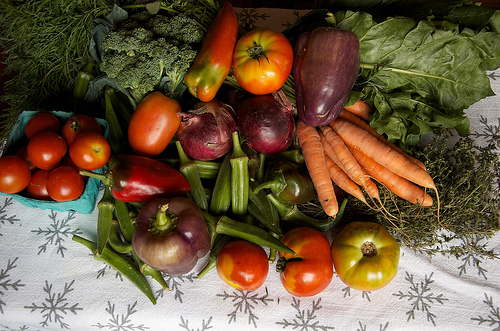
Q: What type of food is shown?
A: Vegetables.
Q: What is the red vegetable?
A: Tomato.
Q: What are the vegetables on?
A: Table cloth.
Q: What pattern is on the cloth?
A: Snowflakes.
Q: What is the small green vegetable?
A: Okra.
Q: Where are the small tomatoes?
A: Cardboard container.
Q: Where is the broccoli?
A: Above the carton.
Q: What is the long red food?
A: Pepper.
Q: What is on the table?
A: Leaves.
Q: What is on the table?
A: Pepper.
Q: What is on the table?
A: Broccoli.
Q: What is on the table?
A: Salad.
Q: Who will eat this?
A: A vegetarian.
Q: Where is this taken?
A: On a table.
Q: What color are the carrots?
A: Orange.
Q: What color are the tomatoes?
A: Red.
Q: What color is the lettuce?
A: Green.